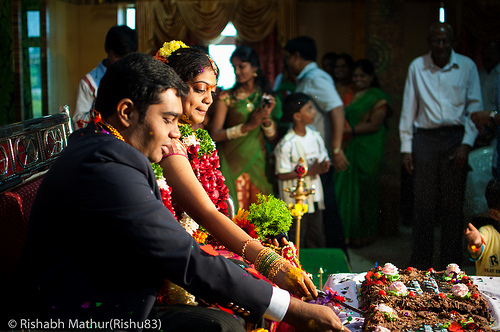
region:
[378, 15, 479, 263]
man with a white shirt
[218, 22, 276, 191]
lady with a green dress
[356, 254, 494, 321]
a cake with flowers on the top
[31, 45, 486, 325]
man and woman cutting a cake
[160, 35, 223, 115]
lady with yellow flowers in here hair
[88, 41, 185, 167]
man with yellow necklace around neck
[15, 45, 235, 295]
man and lady sitting on the chair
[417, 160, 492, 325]
boy pointing at the cake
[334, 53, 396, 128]
lady smiling in the backgrown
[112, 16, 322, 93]
gold curtain on the window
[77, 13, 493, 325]
a couple cutting a cake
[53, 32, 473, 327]
a newlywed couple at a reception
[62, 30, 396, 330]
a Hindi couple at their wedding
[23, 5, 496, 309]
a Hindi wedding reception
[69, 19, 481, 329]
a newlywed couple cutting their cake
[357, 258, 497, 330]
a chocolate cake decorated with flowers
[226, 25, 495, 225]
guests at a wedding reception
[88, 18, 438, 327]
two people cutting cake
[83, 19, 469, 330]
a man and a woman cutting a cake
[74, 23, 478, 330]
an Indian couple at their wedding reception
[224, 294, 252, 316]
four gold cuff links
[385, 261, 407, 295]
pink flowers on cake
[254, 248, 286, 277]
rows of bracelets on women's wrist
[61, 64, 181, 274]
man wearing black suit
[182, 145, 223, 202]
red flowers on wonman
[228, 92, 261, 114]
gold necklace around women's neck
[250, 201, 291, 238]
small green bush in women's hand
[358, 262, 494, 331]
two cakes side by side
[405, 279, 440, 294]
blue writing on cake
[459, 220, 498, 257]
hand of a small child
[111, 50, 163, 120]
Person has dark hair.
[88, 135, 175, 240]
Person wearing blue jacket.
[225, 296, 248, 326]
Gold buttons on jacket sleeve.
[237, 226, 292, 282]
Bracelets around woman's arm.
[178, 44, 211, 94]
Woman has dark hair.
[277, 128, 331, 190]
Person wearing white shirt.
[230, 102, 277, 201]
Woman wearing green dress.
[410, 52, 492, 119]
Man wearing white shirt.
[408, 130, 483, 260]
Man wearing gray pants.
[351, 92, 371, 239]
Woman wearing green dress.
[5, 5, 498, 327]
an Indian wedding reception taking place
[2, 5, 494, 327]
a bridge and groom cutting their cake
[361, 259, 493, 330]
a chocolate cake with flowers on it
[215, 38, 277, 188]
a woman wearing a green dress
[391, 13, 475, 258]
a man wearing a white shirt and black pants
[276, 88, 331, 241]
a child looking off to the side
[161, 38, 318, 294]
a woman wearing flowers around her neck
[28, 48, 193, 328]
a man wearing a gray suit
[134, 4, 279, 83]
a window with an open red curtain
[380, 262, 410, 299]
two pink roses on the wedding cake